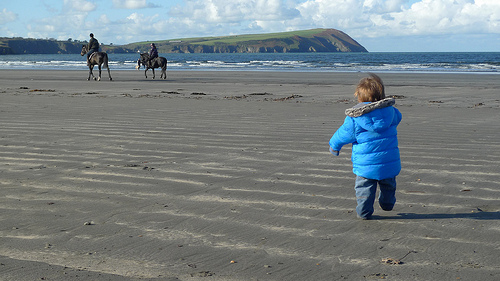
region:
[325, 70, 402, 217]
A SMALL CHILD WALKING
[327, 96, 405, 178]
THE SMALL CHILD HAVE ON BLUE JACKET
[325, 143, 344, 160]
THE SMALL CHILD HAVE ON BLUE MITTEN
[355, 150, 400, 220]
THE SMALL CHILD HAVE ON BLUE JEAN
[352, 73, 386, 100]
THE SMALL CHILD HAVE GOLD HAIR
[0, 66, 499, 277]
THE SMALL CHILD WALKING ON BEACH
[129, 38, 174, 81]
MAN RIDING ON HORSE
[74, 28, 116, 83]
ANOTHER MAN RIDING ON HORSE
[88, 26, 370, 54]
AGREEN HILL SIDE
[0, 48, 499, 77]
A GREAT LAKE OF WATER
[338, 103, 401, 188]
blue puffy coat on a child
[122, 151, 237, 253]
tracks in the sand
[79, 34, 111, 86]
a person on horseback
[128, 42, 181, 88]
a person on horseback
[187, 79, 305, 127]
tracks on the beach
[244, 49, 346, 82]
waves crashing on the shore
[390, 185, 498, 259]
a shadow from a child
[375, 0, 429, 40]
white billowy clouds in the sky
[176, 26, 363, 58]
a cliffside in the distance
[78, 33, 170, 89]
two people riding on a horse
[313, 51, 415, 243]
this is a boy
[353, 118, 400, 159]
this is a jacket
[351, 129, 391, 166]
the jacket is blue in color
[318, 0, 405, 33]
this is the sky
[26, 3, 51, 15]
the sky is blue in color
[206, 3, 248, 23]
these are the clouds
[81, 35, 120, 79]
this is a man riding on the horse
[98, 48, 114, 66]
the horse is black in color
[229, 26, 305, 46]
this is a hill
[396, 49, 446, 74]
this is a water body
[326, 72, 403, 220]
small child walking on the beach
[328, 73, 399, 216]
infant walking towards the beach waves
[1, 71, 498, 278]
brown sand washed up on the shore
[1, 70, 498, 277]
doesnt show signs of sea shells from water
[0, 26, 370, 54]
large mass of green land on other side of water mass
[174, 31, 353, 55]
very steep rocky edge goes striaght down into water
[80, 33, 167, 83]
two people riding horses on the beach front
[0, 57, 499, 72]
white foamy waves rolling in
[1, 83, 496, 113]
disturbed sand on beach shows people were walking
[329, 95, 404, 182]
very large warm coat on infant shows cold weather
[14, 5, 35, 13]
this is the sky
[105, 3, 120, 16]
the sky is blue in color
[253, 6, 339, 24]
the sky has clouds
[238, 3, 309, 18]
the clouds are white in color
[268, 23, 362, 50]
this is a cliff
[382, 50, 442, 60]
this is the water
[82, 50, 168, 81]
these are two horses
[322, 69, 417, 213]
this is a child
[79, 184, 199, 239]
this is the ground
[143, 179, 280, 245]
the sand is grey in color